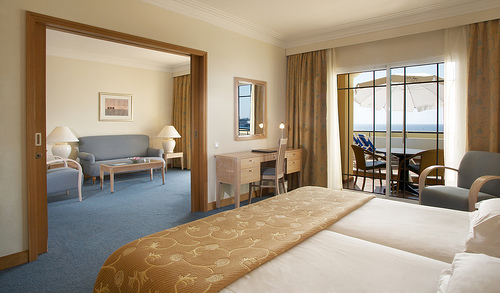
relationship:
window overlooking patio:
[336, 62, 444, 199] [355, 131, 437, 198]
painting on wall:
[74, 84, 134, 126] [75, 65, 145, 132]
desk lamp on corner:
[269, 112, 299, 153] [227, 40, 314, 131]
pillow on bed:
[473, 194, 499, 232] [95, 182, 470, 291]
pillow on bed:
[464, 198, 500, 258] [95, 182, 470, 291]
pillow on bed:
[438, 253, 500, 293] [95, 182, 470, 291]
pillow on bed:
[438, 267, 450, 291] [95, 182, 470, 291]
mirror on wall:
[233, 83, 265, 138] [3, 0, 283, 253]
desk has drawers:
[216, 144, 277, 178] [236, 158, 258, 183]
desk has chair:
[216, 144, 277, 178] [265, 148, 290, 190]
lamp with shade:
[49, 124, 85, 161] [37, 119, 73, 139]